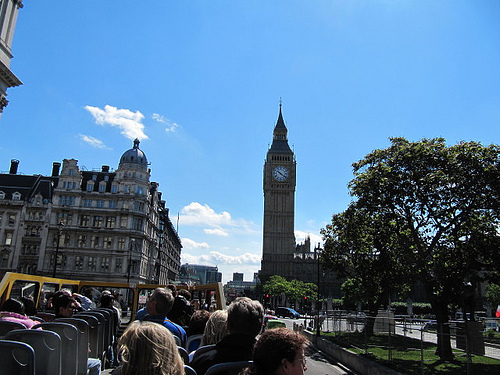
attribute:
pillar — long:
[256, 137, 303, 264]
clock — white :
[260, 91, 300, 286]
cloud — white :
[73, 132, 113, 154]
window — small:
[114, 232, 129, 254]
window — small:
[77, 213, 89, 229]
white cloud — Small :
[178, 193, 245, 235]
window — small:
[91, 211, 107, 228]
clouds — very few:
[88, 97, 137, 132]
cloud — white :
[81, 104, 150, 142]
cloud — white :
[155, 16, 339, 108]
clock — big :
[272, 162, 289, 182]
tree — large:
[318, 135, 497, 359]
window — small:
[83, 196, 91, 208]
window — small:
[95, 196, 103, 209]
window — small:
[109, 199, 119, 211]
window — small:
[113, 254, 123, 272]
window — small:
[99, 254, 110, 271]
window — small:
[92, 212, 101, 231]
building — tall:
[258, 97, 297, 282]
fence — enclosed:
[315, 307, 485, 370]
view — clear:
[0, 1, 499, 284]